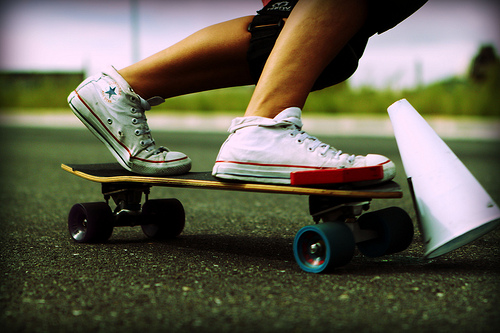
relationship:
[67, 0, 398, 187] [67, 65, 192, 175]
person wearing shoe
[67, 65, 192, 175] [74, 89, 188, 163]
shoe have line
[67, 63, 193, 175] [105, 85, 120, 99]
shoe has star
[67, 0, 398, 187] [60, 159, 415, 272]
person on skateboard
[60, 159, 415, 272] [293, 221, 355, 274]
skateboard has wheel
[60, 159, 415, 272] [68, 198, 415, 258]
skateboard has wheels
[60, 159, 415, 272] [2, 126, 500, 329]
skateboard on concrete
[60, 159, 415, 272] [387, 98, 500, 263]
skateboard near cone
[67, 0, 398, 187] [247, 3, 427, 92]
person wearing shorts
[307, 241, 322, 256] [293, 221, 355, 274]
screw holding wheel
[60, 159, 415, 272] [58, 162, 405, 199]
skateboard has trim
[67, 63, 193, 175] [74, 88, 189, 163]
shoe has line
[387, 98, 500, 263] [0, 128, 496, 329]
cone on street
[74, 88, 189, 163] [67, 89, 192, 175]
line around base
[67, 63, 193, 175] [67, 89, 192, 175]
shoe has base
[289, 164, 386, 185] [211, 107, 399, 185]
object next to foot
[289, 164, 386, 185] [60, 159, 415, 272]
object on top of skateboard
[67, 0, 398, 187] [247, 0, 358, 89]
person wearing knee brace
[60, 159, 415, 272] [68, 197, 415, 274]
skateboard has wheels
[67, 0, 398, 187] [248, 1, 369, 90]
person has left knee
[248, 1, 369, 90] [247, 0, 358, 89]
left knee wearing knee brace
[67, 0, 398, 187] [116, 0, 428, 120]
person has legs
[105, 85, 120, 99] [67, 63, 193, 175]
star on shoe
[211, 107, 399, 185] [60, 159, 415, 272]
foot on skateboard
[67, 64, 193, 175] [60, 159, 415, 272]
foot leaning on skateboard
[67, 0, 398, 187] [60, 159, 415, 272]
person riding skateboard